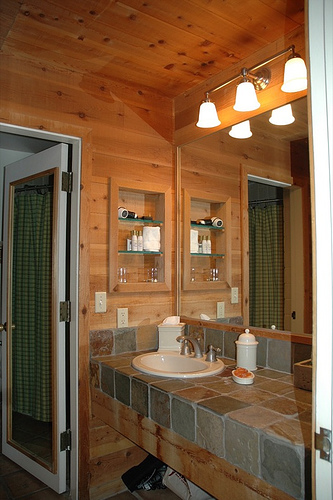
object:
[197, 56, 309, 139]
sconce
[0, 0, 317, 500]
bathroom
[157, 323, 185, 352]
tissue holder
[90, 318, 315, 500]
counter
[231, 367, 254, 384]
soap dish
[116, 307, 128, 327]
electrical outlet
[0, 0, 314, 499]
wall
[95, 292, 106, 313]
light switch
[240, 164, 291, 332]
reflection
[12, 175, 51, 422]
curtain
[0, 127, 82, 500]
door frame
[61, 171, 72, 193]
hinge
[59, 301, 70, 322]
hinge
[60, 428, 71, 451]
hinge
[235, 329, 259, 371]
container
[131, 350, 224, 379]
sink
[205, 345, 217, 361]
right handle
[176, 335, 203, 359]
faucet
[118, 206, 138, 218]
hair dryer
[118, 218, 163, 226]
shelf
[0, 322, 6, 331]
door knob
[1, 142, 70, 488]
door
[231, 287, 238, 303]
reflection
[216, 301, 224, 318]
reflection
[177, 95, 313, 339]
mirror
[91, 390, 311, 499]
base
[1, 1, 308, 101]
ceiling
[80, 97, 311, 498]
vanity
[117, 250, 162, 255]
shelf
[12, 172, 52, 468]
mirror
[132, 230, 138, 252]
bottle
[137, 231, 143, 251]
bottle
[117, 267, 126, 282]
drinking glass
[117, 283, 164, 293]
shelf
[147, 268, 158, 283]
drinking glass